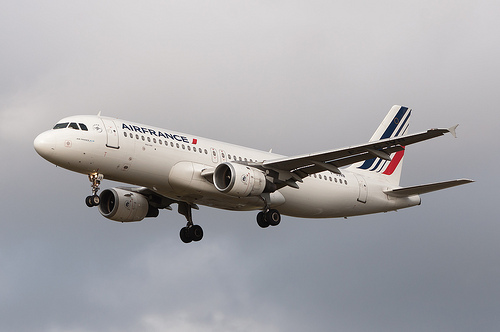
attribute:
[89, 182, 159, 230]
engine — right jet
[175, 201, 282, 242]
landing gear — commercial jet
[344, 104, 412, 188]
tail — planes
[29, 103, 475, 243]
jet — air france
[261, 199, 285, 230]
black tire — round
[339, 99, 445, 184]
tail — red, blue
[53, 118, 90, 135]
windshield — commercial, jet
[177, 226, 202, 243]
tire — round, black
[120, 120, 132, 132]
letter — black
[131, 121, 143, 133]
letter — black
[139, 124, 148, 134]
letter — black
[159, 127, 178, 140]
letter — black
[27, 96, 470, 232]
plane — white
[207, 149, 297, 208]
engine — planes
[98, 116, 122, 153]
door — white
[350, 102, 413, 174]
jet tail — commercial 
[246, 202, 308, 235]
wheels — rear, jets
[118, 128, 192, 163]
window — small